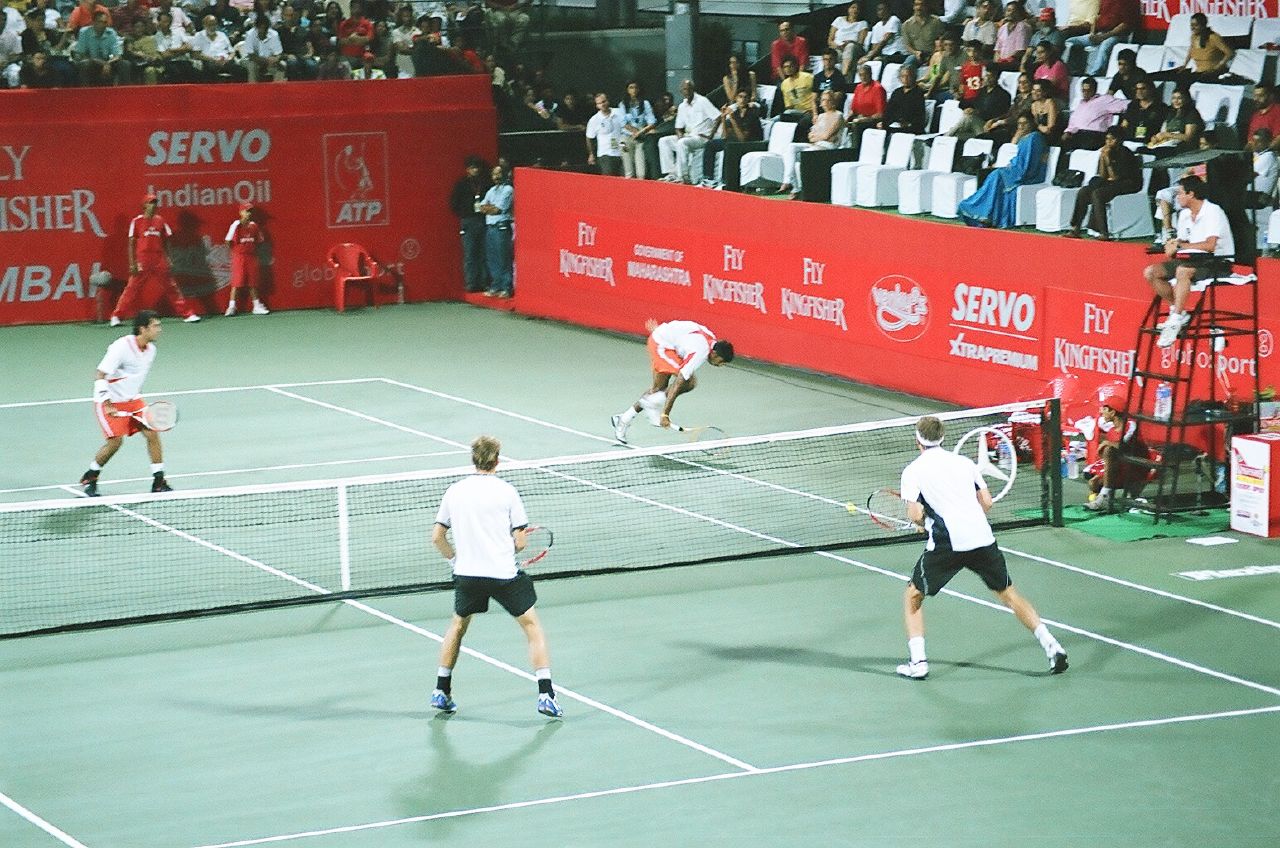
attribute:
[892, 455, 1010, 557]
shirt — black, white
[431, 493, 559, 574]
top — white 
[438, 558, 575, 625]
short — black 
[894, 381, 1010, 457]
headband — white 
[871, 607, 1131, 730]
shoes — white 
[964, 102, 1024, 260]
dress — long , blue 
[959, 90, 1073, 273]
chair — white 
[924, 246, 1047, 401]
letters — white , large 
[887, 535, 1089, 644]
shorts — black 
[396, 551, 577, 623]
shorts — black 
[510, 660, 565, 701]
socks — black 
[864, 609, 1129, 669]
socks — white 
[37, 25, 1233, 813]
scene — outdoors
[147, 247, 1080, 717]
people — playing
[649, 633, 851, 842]
court — green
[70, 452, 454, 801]
net — black, white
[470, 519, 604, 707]
shorts — black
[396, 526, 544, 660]
shorts — black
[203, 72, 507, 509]
wall — red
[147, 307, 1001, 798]
men — playing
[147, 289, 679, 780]
lines — white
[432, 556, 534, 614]
shorts — black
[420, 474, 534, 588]
shirt — white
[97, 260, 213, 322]
legs — far apart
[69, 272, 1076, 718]
men — tennis-playing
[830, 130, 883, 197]
chair — white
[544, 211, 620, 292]
logo — white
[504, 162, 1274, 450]
banner — red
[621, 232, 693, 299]
logo — white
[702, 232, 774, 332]
logo — white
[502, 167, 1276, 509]
banner — red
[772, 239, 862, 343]
logo — white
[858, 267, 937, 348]
logo — white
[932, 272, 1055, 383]
logo — white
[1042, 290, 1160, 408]
logo — white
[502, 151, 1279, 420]
banner — red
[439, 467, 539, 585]
shirt — white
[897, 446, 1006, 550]
shirt — white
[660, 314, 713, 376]
shirt — white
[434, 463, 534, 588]
shirt — white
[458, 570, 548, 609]
shorts — black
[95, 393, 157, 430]
shorts — red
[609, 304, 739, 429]
tennis player — ball-diving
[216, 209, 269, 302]
clothing — red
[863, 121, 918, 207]
chair — white